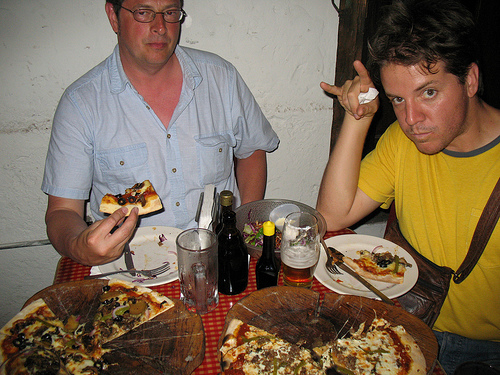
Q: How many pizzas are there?
A: 2.